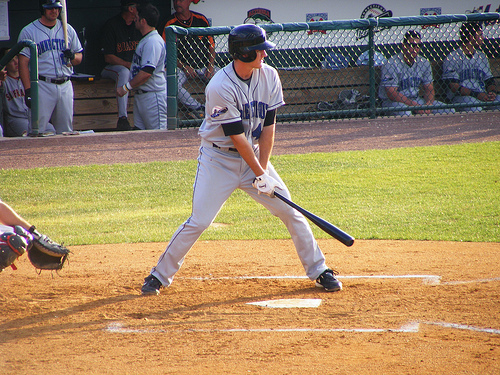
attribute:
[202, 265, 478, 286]
line — white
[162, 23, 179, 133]
post — fence post, green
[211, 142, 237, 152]
belt — is black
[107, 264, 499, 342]
lines — are white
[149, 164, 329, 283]
legs — spread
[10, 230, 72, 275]
glove — leather 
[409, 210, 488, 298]
dirt — brown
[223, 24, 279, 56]
baseball cap — dark, blue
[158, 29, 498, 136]
fence — green, chain link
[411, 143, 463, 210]
grass — green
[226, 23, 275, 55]
helmet — blue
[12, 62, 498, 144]
bench — wooden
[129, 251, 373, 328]
sneakers — blue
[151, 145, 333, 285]
pants — are gray , white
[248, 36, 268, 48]
helmet — stripe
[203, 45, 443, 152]
bench — wooden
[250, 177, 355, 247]
bat — black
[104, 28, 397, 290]
player — black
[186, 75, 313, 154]
shirt — orange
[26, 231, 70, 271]
glove — brown, black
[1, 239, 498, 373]
sand — orange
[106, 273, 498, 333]
lines — white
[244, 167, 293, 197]
gloves — are white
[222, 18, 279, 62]
helmet — black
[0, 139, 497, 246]
grass — green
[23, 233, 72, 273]
glove — black, brown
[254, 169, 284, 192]
glove — white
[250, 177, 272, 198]
glove — white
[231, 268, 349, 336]
home plate — white